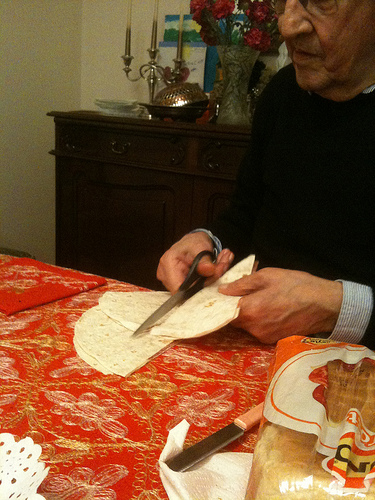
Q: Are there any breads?
A: Yes, there is a bread.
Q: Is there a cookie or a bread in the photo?
A: Yes, there is a bread.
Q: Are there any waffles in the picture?
A: No, there are no waffles.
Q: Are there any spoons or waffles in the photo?
A: No, there are no waffles or spoons.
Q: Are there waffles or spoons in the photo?
A: No, there are no waffles or spoons.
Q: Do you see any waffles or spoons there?
A: No, there are no waffles or spoons.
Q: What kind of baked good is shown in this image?
A: The baked good is a bread.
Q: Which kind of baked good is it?
A: The food is a bread.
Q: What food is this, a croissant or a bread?
A: That is a bread.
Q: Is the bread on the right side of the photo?
A: Yes, the bread is on the right of the image.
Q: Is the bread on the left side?
A: No, the bread is on the right of the image.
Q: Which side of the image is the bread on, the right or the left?
A: The bread is on the right of the image.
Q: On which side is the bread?
A: The bread is on the right of the image.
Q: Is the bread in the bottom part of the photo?
A: Yes, the bread is in the bottom of the image.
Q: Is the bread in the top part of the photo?
A: No, the bread is in the bottom of the image.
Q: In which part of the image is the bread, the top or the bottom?
A: The bread is in the bottom of the image.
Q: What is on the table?
A: The bread is on the table.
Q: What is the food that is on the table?
A: The food is a bread.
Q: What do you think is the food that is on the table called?
A: The food is a bread.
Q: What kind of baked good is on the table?
A: The food is a bread.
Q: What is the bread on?
A: The bread is on the table.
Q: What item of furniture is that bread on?
A: The bread is on the table.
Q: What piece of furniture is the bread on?
A: The bread is on the table.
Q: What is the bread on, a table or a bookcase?
A: The bread is on a table.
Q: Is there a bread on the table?
A: Yes, there is a bread on the table.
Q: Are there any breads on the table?
A: Yes, there is a bread on the table.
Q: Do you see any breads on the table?
A: Yes, there is a bread on the table.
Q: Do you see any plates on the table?
A: No, there is a bread on the table.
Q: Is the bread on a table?
A: Yes, the bread is on a table.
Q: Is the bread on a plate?
A: No, the bread is on a table.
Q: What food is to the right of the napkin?
A: The food is a bread.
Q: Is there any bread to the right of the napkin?
A: Yes, there is a bread to the right of the napkin.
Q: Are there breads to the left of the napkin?
A: No, the bread is to the right of the napkin.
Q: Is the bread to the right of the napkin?
A: Yes, the bread is to the right of the napkin.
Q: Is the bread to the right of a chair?
A: No, the bread is to the right of the napkin.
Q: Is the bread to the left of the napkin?
A: No, the bread is to the right of the napkin.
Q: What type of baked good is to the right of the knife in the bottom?
A: The food is a bread.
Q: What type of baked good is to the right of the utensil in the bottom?
A: The food is a bread.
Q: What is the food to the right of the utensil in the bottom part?
A: The food is a bread.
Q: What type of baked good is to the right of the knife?
A: The food is a bread.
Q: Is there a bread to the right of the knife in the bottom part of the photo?
A: Yes, there is a bread to the right of the knife.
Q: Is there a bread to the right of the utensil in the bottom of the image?
A: Yes, there is a bread to the right of the knife.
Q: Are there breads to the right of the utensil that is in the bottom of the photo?
A: Yes, there is a bread to the right of the knife.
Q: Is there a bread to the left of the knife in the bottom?
A: No, the bread is to the right of the knife.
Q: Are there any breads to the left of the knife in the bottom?
A: No, the bread is to the right of the knife.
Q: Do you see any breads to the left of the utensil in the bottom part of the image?
A: No, the bread is to the right of the knife.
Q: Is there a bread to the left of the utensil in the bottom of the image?
A: No, the bread is to the right of the knife.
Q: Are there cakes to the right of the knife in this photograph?
A: No, there is a bread to the right of the knife.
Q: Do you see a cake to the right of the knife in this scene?
A: No, there is a bread to the right of the knife.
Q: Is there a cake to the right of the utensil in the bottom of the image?
A: No, there is a bread to the right of the knife.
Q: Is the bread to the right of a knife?
A: Yes, the bread is to the right of a knife.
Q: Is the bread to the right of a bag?
A: No, the bread is to the right of a knife.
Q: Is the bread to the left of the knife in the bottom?
A: No, the bread is to the right of the knife.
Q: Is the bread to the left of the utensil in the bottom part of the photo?
A: No, the bread is to the right of the knife.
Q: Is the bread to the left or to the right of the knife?
A: The bread is to the right of the knife.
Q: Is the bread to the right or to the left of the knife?
A: The bread is to the right of the knife.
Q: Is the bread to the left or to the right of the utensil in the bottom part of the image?
A: The bread is to the right of the knife.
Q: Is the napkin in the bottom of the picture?
A: Yes, the napkin is in the bottom of the image.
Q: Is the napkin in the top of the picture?
A: No, the napkin is in the bottom of the image.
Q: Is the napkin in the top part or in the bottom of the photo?
A: The napkin is in the bottom of the image.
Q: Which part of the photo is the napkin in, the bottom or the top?
A: The napkin is in the bottom of the image.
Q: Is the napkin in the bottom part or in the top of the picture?
A: The napkin is in the bottom of the image.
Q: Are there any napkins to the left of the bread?
A: Yes, there is a napkin to the left of the bread.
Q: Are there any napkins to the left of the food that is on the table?
A: Yes, there is a napkin to the left of the bread.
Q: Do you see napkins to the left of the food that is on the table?
A: Yes, there is a napkin to the left of the bread.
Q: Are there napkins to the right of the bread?
A: No, the napkin is to the left of the bread.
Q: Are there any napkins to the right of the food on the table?
A: No, the napkin is to the left of the bread.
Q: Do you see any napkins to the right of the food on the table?
A: No, the napkin is to the left of the bread.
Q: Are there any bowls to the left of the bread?
A: No, there is a napkin to the left of the bread.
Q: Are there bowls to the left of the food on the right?
A: No, there is a napkin to the left of the bread.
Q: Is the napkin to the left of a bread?
A: Yes, the napkin is to the left of a bread.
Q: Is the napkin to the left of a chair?
A: No, the napkin is to the left of a bread.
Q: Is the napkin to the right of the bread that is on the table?
A: No, the napkin is to the left of the bread.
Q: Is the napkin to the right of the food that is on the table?
A: No, the napkin is to the left of the bread.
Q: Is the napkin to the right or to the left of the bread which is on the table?
A: The napkin is to the left of the bread.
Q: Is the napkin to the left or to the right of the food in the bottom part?
A: The napkin is to the left of the bread.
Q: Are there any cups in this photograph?
A: No, there are no cups.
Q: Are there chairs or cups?
A: No, there are no cups or chairs.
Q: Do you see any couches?
A: No, there are no couches.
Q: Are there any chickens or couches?
A: No, there are no couches or chickens.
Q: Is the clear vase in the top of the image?
A: Yes, the vase is in the top of the image.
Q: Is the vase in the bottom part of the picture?
A: No, the vase is in the top of the image.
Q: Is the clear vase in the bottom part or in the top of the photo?
A: The vase is in the top of the image.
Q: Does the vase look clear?
A: Yes, the vase is clear.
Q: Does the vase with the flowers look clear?
A: Yes, the vase is clear.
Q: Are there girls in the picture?
A: No, there are no girls.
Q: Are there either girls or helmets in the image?
A: No, there are no girls or helmets.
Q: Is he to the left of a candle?
A: No, the man is to the right of a candle.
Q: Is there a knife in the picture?
A: Yes, there is a knife.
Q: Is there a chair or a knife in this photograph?
A: Yes, there is a knife.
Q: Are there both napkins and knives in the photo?
A: Yes, there are both a knife and a napkin.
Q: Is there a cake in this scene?
A: No, there are no cakes.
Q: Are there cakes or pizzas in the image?
A: No, there are no cakes or pizzas.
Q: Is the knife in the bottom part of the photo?
A: Yes, the knife is in the bottom of the image.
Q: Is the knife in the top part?
A: No, the knife is in the bottom of the image.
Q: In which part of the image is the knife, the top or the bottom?
A: The knife is in the bottom of the image.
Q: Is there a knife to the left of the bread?
A: Yes, there is a knife to the left of the bread.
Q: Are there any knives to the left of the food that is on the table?
A: Yes, there is a knife to the left of the bread.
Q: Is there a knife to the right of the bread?
A: No, the knife is to the left of the bread.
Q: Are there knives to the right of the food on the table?
A: No, the knife is to the left of the bread.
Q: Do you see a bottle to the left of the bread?
A: No, there is a knife to the left of the bread.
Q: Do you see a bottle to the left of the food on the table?
A: No, there is a knife to the left of the bread.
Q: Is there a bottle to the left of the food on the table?
A: No, there is a knife to the left of the bread.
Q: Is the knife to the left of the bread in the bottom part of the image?
A: Yes, the knife is to the left of the bread.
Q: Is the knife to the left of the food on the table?
A: Yes, the knife is to the left of the bread.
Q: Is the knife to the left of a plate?
A: No, the knife is to the left of the bread.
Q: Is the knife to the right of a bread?
A: No, the knife is to the left of a bread.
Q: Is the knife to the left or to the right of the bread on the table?
A: The knife is to the left of the bread.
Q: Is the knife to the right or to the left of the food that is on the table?
A: The knife is to the left of the bread.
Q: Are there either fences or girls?
A: No, there are no girls or fences.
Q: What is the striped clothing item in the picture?
A: The clothing item is a shirt.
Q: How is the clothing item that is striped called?
A: The clothing item is a shirt.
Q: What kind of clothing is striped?
A: The clothing is a shirt.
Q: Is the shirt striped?
A: Yes, the shirt is striped.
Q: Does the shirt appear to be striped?
A: Yes, the shirt is striped.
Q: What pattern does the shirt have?
A: The shirt has striped pattern.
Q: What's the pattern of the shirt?
A: The shirt is striped.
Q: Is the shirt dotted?
A: No, the shirt is striped.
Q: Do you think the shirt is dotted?
A: No, the shirt is striped.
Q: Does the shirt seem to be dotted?
A: No, the shirt is striped.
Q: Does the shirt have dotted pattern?
A: No, the shirt is striped.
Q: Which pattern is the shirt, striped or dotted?
A: The shirt is striped.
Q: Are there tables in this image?
A: Yes, there is a table.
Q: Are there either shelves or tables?
A: Yes, there is a table.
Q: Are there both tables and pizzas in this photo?
A: No, there is a table but no pizzas.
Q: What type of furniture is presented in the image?
A: The furniture is a table.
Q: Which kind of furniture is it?
A: The piece of furniture is a table.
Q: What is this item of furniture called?
A: This is a table.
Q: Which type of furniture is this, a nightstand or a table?
A: This is a table.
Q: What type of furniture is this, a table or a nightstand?
A: This is a table.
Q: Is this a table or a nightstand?
A: This is a table.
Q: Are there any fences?
A: No, there are no fences.